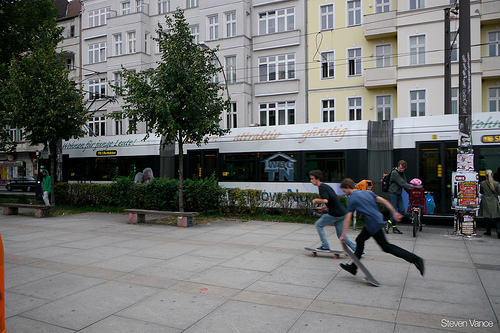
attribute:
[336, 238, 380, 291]
skateboard — black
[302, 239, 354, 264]
skateboard — black, long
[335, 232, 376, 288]
skateboard — long, black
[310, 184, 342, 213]
shirt — black, short sleeve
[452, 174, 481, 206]
sign — large, red